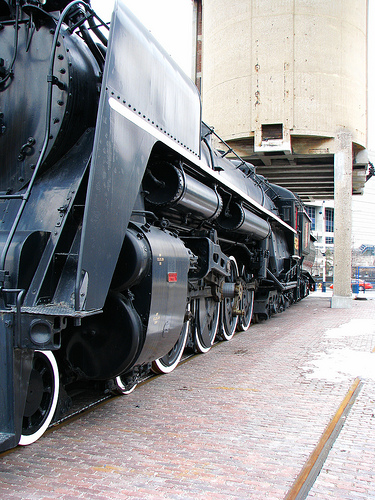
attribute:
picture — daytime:
[0, 3, 372, 499]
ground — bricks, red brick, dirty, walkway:
[0, 296, 374, 499]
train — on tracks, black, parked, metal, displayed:
[1, 1, 316, 446]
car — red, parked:
[331, 276, 373, 294]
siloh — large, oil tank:
[191, 1, 374, 309]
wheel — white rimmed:
[4, 340, 59, 456]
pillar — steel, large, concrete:
[332, 141, 358, 307]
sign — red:
[302, 222, 312, 252]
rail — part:
[52, 341, 222, 427]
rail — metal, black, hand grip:
[200, 118, 279, 196]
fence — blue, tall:
[351, 264, 374, 293]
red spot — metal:
[167, 274, 182, 284]